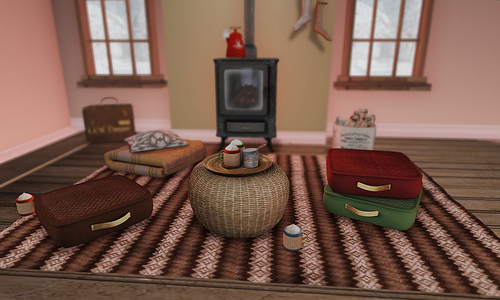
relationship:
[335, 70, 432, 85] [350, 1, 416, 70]
windowsill under window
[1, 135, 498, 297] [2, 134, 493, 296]
rug on floor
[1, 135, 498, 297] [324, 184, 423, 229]
rug on container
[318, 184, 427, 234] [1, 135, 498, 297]
container on rug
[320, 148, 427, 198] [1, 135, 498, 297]
container on rug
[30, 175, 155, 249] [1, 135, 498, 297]
suitcase on rug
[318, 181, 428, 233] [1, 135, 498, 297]
suitcase on rug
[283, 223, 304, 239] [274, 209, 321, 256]
whipped cream in cup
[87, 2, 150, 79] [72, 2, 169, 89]
window in frame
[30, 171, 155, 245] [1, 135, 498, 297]
suitcase on eth rug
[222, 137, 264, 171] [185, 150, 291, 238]
cups on ottoman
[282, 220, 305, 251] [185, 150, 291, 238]
cups on ottoman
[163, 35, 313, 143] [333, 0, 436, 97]
stove beside window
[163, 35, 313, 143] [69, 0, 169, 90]
stove beside window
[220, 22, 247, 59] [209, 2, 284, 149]
red kettle on stove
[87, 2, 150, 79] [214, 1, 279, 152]
window beside stove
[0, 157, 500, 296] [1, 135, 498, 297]
stripe on rug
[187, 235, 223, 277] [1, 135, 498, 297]
stripe on rug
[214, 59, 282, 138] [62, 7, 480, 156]
fireplace against wall